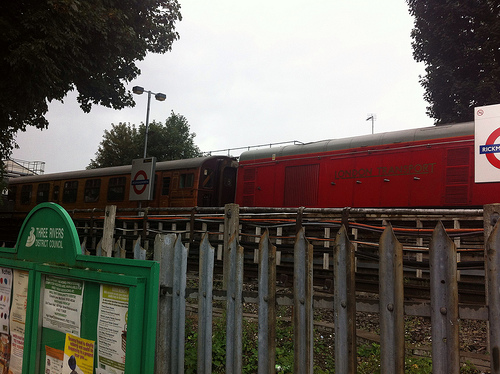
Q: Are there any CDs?
A: No, there are no cds.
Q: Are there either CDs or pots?
A: No, there are no CDs or pots.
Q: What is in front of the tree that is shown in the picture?
A: The lamp post is in front of the tree.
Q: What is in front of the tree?
A: The lamp post is in front of the tree.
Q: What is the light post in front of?
A: The light post is in front of the tree.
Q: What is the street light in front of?
A: The light post is in front of the tree.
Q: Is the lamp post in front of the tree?
A: Yes, the lamp post is in front of the tree.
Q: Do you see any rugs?
A: No, there are no rugs.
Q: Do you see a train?
A: Yes, there is a train.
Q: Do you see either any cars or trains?
A: Yes, there is a train.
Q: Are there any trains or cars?
A: Yes, there is a train.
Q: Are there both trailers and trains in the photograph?
A: No, there is a train but no trailers.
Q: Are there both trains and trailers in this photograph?
A: No, there is a train but no trailers.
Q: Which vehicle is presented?
A: The vehicle is a train.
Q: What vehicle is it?
A: The vehicle is a train.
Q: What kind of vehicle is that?
A: This is a train.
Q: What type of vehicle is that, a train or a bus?
A: This is a train.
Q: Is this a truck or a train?
A: This is a train.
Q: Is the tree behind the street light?
A: Yes, the tree is behind the street light.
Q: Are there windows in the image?
A: Yes, there is a window.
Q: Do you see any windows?
A: Yes, there is a window.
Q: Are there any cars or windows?
A: Yes, there is a window.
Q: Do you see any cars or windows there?
A: Yes, there is a window.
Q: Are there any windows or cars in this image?
A: Yes, there is a window.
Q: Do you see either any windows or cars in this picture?
A: Yes, there is a window.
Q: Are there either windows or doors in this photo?
A: Yes, there is a window.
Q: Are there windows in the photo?
A: Yes, there is a window.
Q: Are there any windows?
A: Yes, there is a window.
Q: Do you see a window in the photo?
A: Yes, there is a window.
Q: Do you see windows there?
A: Yes, there is a window.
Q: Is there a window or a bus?
A: Yes, there is a window.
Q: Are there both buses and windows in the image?
A: No, there is a window but no buses.